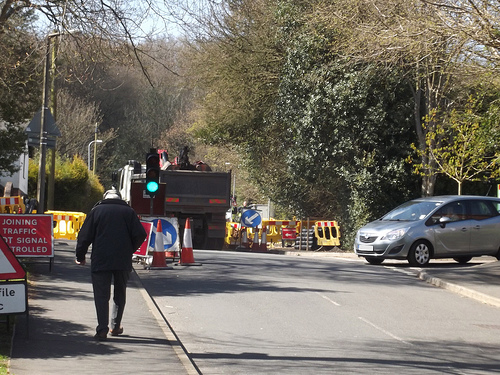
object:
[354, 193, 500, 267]
car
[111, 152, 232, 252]
large truck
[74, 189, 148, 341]
man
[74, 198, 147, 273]
jacket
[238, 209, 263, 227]
sign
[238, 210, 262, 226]
arrow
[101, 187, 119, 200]
hat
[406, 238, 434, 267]
tire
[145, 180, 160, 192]
light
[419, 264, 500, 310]
curb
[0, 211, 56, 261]
sign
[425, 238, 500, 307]
sidewalk